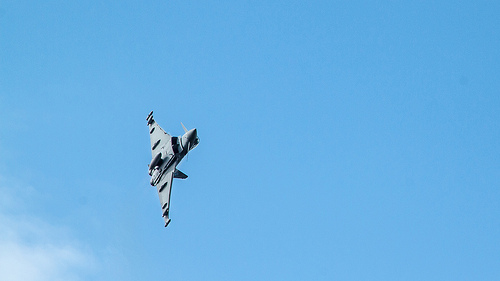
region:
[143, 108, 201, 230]
A jet in the sky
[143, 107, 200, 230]
A jet in the sky soaring downwards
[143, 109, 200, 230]
A jet flying high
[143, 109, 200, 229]
A jet flying high in the blue sky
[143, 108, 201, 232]
A grey jet flying high in the blue sky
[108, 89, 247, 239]
plane in the air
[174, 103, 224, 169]
front of the plane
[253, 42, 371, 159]
blue sky in the background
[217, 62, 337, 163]
sky behind the plane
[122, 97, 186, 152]
wing of the plane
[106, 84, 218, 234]
plane with two wings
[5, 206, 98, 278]
white cloud in the sky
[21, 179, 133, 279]
clouds behind the plane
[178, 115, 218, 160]
tip of the plane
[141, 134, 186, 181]
body of the plane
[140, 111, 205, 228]
gray military aircraft in the sky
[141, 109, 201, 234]
gray plane in the sky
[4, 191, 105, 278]
puff of white cloud in the corner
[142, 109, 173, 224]
wings of the plane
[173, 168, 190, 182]
tail of the plane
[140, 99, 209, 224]
the plane is tilted on its side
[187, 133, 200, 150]
cockpit on the underside of the plane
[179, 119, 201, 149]
propellor on the front of the plane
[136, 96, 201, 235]
gray military plane doing a drill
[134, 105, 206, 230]
gray jet in the sky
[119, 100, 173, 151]
wing on the plane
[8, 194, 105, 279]
clouds in the sky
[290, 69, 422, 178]
blue sky in the background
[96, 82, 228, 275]
silver plane in the air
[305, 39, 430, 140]
blue sky with no clouds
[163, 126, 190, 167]
windows on the plane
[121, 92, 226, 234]
one plane with clouds behind it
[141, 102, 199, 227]
Plane in the air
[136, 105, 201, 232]
Plane is in the air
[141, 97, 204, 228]
Airplane in the air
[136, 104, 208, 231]
Airplane is in the air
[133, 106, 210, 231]
Fighter plane in the air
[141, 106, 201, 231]
Fighter plane is in the air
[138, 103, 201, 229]
Plane flying in the air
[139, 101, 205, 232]
Plane is flying in the air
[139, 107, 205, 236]
Fighter plane flying in the air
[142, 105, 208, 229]
Fighter plane is flying in the air